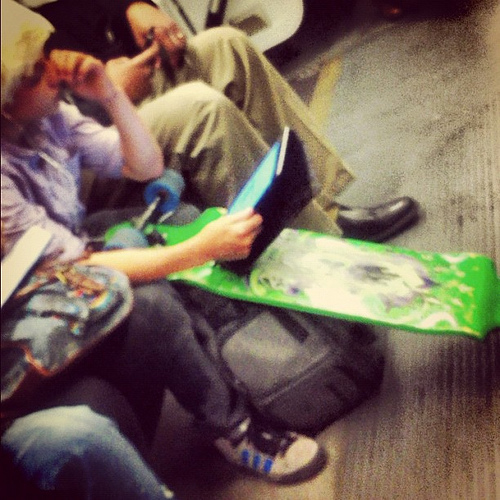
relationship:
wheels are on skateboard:
[149, 178, 189, 205] [137, 194, 484, 329]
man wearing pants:
[38, 0, 434, 278] [152, 0, 360, 221]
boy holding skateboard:
[4, 18, 388, 485] [107, 167, 499, 342]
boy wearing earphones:
[0, 0, 329, 487] [4, 88, 26, 124]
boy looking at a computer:
[0, 0, 329, 487] [227, 125, 322, 280]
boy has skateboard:
[0, 0, 329, 487] [107, 167, 499, 342]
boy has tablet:
[0, 0, 329, 487] [215, 120, 320, 289]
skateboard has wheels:
[107, 167, 499, 342] [99, 167, 195, 259]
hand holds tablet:
[202, 202, 265, 271] [215, 120, 320, 289]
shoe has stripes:
[204, 413, 336, 496] [235, 444, 276, 482]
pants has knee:
[8, 394, 184, 497] [13, 394, 122, 479]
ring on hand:
[173, 27, 187, 41] [122, 2, 191, 67]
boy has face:
[0, 0, 329, 487] [15, 45, 67, 130]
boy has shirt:
[0, 0, 329, 487] [2, 98, 131, 258]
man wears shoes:
[16, 0, 421, 243] [321, 189, 431, 241]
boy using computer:
[0, 0, 329, 487] [203, 111, 294, 258]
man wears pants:
[16, 0, 421, 243] [97, 24, 356, 240]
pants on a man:
[97, 24, 347, 240] [16, 0, 421, 243]